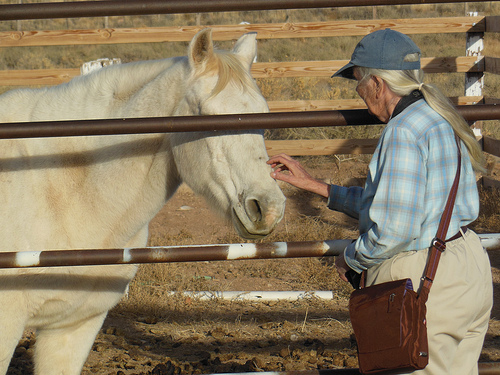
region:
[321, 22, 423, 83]
grey baseball cap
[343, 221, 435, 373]
small brown messenger bag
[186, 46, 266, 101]
blond hair on crown of horse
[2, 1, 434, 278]
brown metal and white fence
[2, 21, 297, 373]
white horse behind fence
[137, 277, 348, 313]
white pole in ground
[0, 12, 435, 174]
light wood fence behind white horse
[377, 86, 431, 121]
black collar on blue plaid shirt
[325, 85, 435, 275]
blue, white and tan plaid long sleeve shirt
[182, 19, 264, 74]
two pointed horse ears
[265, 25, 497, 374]
Older woman petting white horse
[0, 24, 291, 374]
White horse behind the fence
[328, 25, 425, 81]
Blue baseball cap on the woman's head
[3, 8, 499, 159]
Wooden fence behind the horse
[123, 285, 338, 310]
White PVC pile behind the horse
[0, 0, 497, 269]
Brown metal fencing in front of the horse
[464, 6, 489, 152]
Post on the right with flaking paint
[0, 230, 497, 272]
Round piping with white paint on it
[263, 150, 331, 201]
Right hand of the woman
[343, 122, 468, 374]
Brown handbag with strap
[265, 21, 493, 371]
An old lady wearing a cap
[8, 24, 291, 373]
A white horse inside a barricade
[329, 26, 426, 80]
a blue baseball cap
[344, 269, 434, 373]
a brown carrying bag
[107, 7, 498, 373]
An old lady is comforting a horse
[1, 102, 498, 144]
A steel rusty bar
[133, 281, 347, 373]
A rocky plain field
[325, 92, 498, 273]
A stripped collar blue dress shirt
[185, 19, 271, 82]
ear of an horse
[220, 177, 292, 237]
the jaw of an horse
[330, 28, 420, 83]
the hat on the old woman's head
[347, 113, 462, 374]
the bag hanging off the woman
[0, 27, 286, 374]
the horse in the enclosure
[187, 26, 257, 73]
the ears on the horse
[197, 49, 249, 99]
the mane on the horse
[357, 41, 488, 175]
the hair on the old woman's head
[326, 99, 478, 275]
the long sleeved shirt on the woman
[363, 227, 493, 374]
the long pants on the woman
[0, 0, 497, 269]
the metal poles in front of the horse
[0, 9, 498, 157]
the wood pieces behind the horse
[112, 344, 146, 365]
Small clumps of mud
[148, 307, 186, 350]
Small clumps of mud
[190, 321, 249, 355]
Small clumps of mud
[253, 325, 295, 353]
Small clumps of mud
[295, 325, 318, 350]
Small clumps of mud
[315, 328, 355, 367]
Small clumps of mud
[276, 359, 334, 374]
Small clumps of mud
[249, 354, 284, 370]
Small clumps of mud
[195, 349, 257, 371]
Small clumps of mud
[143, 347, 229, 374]
Small clumps of mud